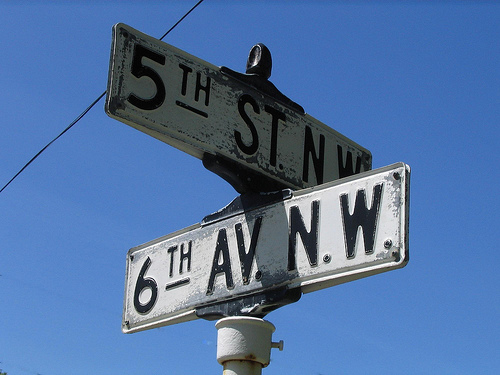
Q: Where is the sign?
A: On a pole.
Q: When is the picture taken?
A: Daytime.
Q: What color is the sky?
A: Blue.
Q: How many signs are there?
A: 2.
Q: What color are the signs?
A: White.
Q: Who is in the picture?
A: No one.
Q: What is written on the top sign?
A: 5th St. NW.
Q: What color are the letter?
A: Black.